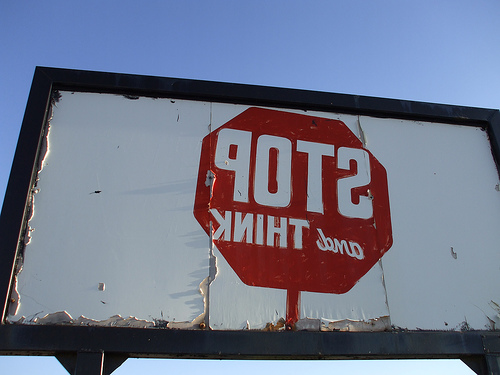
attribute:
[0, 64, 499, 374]
sign — white, damaged, black, billboard, tall, large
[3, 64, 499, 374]
frame — black, wood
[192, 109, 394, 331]
stop sign drawing — red, octagon, white, backwards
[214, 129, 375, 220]
stop letters — white, backwards, capital, written backwards, capital letters, tall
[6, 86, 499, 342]
paper — curled, torn, ripped, puckering, white, ripping away, peeling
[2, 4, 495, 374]
sky — blue, clear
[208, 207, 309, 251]
word think — backwards, written backwards, white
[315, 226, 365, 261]
word and — backwards, scripted writing, cursive, written in cursive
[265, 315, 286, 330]
spot — brown, black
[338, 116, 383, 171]
edge — smooth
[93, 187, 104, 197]
dirt — small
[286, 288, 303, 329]
pole drawing — red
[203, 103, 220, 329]
line — worn